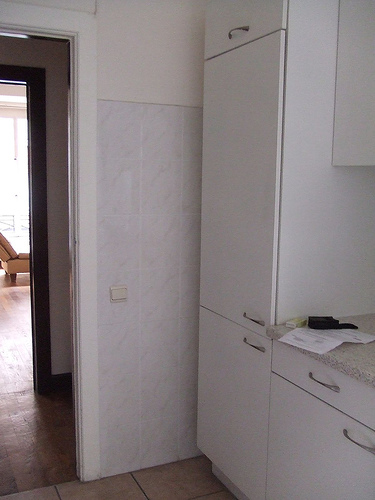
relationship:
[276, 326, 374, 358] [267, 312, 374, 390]
paper on counter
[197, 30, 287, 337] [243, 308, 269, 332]
cabinet with handle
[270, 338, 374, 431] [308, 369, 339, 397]
drawer with handle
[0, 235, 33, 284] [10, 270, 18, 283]
couch has leg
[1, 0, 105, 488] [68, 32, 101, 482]
doorway has jamb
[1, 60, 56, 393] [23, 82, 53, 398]
doorway has jamb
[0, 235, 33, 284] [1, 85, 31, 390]
couch in room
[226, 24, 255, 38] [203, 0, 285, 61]
handle on cabinet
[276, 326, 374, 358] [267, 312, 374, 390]
paperwork on countertop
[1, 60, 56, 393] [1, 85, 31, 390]
doorway to room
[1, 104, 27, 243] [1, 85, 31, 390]
window in room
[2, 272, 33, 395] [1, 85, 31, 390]
flooring in room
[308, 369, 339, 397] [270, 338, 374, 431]
handle on drawer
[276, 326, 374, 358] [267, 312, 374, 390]
paper on top of counter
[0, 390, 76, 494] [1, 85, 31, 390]
hallway in front of room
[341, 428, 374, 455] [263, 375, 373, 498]
handle on cabinet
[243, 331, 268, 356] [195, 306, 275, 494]
handle on cabinet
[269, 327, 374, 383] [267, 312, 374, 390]
edge of counter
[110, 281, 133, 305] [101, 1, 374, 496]
switch in kitchen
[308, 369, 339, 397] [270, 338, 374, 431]
handle for drawer